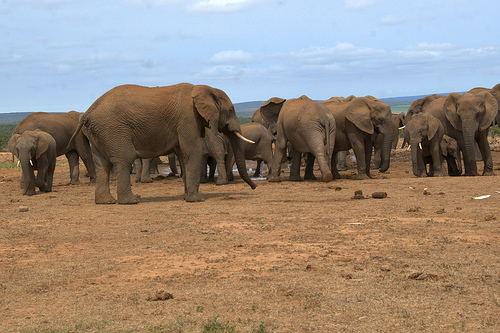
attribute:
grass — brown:
[0, 133, 492, 323]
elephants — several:
[442, 90, 497, 172]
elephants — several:
[413, 132, 461, 173]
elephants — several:
[401, 110, 445, 176]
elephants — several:
[303, 92, 395, 177]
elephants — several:
[269, 97, 336, 178]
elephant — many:
[7, 128, 58, 198]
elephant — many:
[10, 109, 94, 186]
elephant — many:
[423, 81, 499, 176]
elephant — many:
[260, 96, 336, 183]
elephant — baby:
[49, 72, 280, 209]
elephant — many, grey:
[64, 82, 256, 202]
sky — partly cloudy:
[153, 15, 357, 75]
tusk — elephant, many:
[238, 132, 255, 149]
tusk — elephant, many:
[399, 118, 408, 133]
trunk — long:
[229, 118, 256, 189]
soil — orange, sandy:
[3, 172, 495, 326]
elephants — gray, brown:
[4, 76, 497, 206]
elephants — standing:
[14, 91, 484, 210]